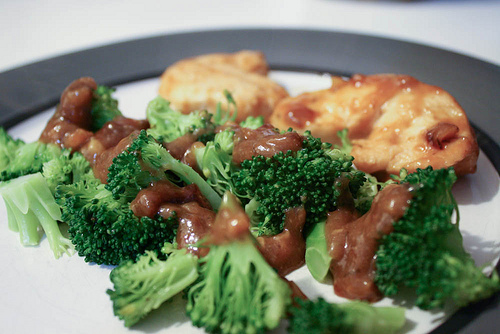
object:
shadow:
[465, 229, 497, 275]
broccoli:
[172, 236, 297, 332]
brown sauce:
[36, 77, 414, 305]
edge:
[0, 26, 497, 130]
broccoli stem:
[9, 174, 66, 253]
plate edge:
[0, 62, 100, 319]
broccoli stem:
[306, 218, 333, 279]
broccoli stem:
[174, 161, 221, 205]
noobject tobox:
[210, 119, 267, 173]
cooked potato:
[281, 66, 476, 194]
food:
[0, 48, 500, 332]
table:
[1, 0, 498, 332]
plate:
[6, 26, 498, 333]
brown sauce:
[252, 211, 308, 273]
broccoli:
[50, 141, 175, 268]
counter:
[1, 3, 498, 50]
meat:
[154, 47, 283, 129]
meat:
[268, 68, 483, 185]